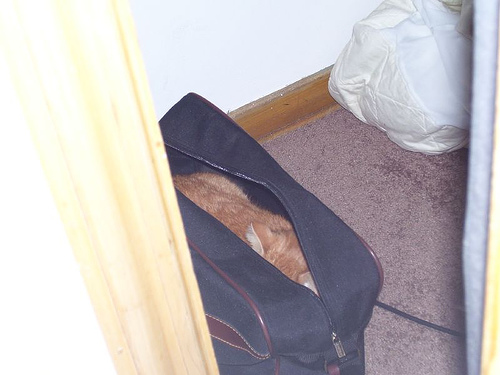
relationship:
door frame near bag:
[21, 0, 199, 372] [148, 90, 363, 371]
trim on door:
[6, 1, 179, 372] [109, 0, 472, 371]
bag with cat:
[154, 87, 389, 374] [180, 164, 316, 287]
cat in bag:
[165, 169, 324, 299] [154, 87, 389, 374]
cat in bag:
[165, 169, 324, 299] [144, 69, 384, 372]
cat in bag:
[177, 163, 336, 303] [154, 87, 389, 374]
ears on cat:
[244, 218, 265, 259] [165, 169, 324, 299]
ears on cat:
[249, 218, 274, 259] [165, 169, 324, 299]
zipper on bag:
[328, 329, 348, 359] [154, 87, 389, 374]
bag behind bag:
[320, 3, 473, 163] [154, 87, 389, 374]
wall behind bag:
[125, 0, 399, 165] [154, 87, 389, 374]